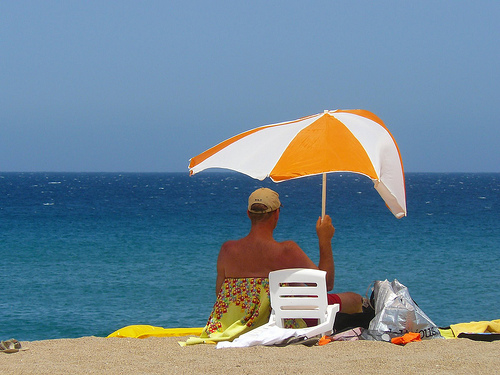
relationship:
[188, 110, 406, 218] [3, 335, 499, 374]
umbrella for beach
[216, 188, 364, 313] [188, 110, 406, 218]
man holding umbrella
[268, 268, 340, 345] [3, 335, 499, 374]
beach chair on beach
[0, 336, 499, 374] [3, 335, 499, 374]
sand on beach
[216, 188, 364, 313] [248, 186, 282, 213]
man wearing hat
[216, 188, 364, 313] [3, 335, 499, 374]
man at beach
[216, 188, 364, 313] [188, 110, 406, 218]
man with umbrella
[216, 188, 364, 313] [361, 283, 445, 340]
man with bag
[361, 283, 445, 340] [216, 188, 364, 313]
bag next to man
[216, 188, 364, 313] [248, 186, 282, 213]
man in hat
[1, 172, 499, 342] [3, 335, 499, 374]
ocean at beach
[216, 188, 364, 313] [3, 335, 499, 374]
man in beach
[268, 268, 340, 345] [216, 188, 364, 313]
beach chair next to man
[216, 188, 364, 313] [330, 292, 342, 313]
man wears shorts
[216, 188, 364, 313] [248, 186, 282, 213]
man wears hat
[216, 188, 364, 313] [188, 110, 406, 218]
man under umbrella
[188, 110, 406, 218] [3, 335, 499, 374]
umbrella on beach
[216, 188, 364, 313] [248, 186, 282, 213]
man with hat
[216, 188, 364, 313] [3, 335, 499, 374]
man on beach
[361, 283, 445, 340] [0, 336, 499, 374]
bag sits in sand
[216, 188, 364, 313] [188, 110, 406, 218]
man holding onto umbrella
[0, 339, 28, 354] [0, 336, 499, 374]
shoe in sand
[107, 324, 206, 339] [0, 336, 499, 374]
beach toy in sand